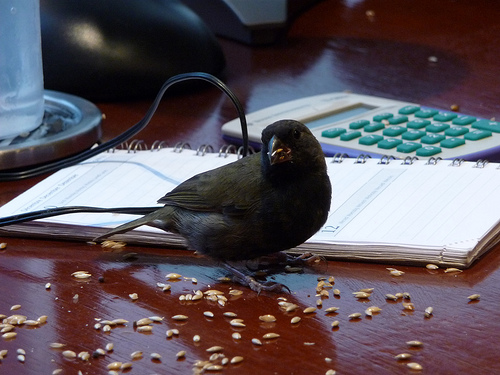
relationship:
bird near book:
[81, 117, 329, 297] [0, 141, 499, 280]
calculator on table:
[224, 81, 499, 168] [7, 6, 495, 374]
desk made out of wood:
[0, 0, 500, 373] [96, 91, 424, 344]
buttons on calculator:
[321, 106, 450, 170] [200, 89, 472, 155]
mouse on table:
[36, 2, 238, 115] [11, 31, 445, 372]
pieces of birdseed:
[394, 336, 425, 368] [379, 334, 431, 368]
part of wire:
[150, 70, 233, 86] [0, 69, 253, 181]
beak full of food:
[262, 132, 297, 169] [0, 239, 439, 373]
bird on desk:
[81, 117, 329, 297] [1, 70, 415, 369]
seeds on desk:
[5, 253, 395, 369] [0, 270, 434, 372]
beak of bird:
[266, 136, 294, 166] [35, 118, 337, 291]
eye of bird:
[284, 120, 313, 149] [73, 106, 343, 302]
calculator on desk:
[219, 90, 499, 166] [7, 2, 471, 372]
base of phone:
[230, 14, 292, 54] [202, 0, 341, 71]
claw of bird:
[232, 249, 350, 298] [81, 117, 329, 297]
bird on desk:
[81, 117, 329, 297] [7, 2, 471, 372]